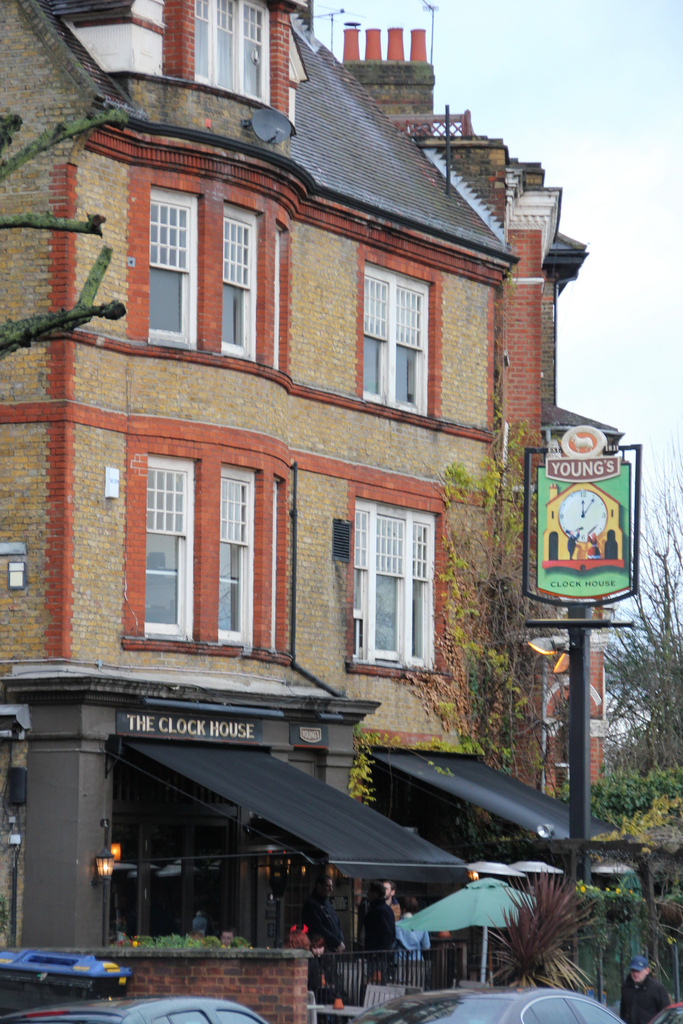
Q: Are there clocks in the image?
A: Yes, there is a clock.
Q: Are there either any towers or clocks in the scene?
A: Yes, there is a clock.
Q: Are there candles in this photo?
A: No, there are no candles.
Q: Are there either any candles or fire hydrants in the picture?
A: No, there are no candles or fire hydrants.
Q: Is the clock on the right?
A: Yes, the clock is on the right of the image.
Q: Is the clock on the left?
A: No, the clock is on the right of the image.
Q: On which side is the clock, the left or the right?
A: The clock is on the right of the image.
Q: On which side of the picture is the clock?
A: The clock is on the right of the image.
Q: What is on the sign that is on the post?
A: The clock is on the sign.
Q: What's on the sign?
A: The clock is on the sign.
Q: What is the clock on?
A: The clock is on the sign.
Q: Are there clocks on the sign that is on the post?
A: Yes, there is a clock on the sign.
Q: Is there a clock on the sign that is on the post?
A: Yes, there is a clock on the sign.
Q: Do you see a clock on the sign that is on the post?
A: Yes, there is a clock on the sign.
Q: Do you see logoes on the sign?
A: No, there is a clock on the sign.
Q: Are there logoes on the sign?
A: No, there is a clock on the sign.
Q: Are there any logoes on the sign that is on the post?
A: No, there is a clock on the sign.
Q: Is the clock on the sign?
A: Yes, the clock is on the sign.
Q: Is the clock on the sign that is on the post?
A: Yes, the clock is on the sign.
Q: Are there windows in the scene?
A: Yes, there is a window.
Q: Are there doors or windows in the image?
A: Yes, there is a window.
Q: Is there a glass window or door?
A: Yes, there is a glass window.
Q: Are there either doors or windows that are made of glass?
A: Yes, the window is made of glass.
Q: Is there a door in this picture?
A: No, there are no doors.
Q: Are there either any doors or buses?
A: No, there are no doors or buses.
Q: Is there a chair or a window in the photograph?
A: Yes, there is a window.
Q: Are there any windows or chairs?
A: Yes, there is a window.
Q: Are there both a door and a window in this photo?
A: No, there is a window but no doors.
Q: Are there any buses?
A: No, there are no buses.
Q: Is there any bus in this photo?
A: No, there are no buses.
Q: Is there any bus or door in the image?
A: No, there are no buses or doors.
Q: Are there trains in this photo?
A: No, there are no trains.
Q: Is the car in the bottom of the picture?
A: Yes, the car is in the bottom of the image.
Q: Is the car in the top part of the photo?
A: No, the car is in the bottom of the image.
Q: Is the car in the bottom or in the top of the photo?
A: The car is in the bottom of the image.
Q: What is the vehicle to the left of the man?
A: The vehicle is a car.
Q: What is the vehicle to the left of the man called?
A: The vehicle is a car.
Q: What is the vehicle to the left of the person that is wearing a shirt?
A: The vehicle is a car.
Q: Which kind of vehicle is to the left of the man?
A: The vehicle is a car.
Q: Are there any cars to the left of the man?
A: Yes, there is a car to the left of the man.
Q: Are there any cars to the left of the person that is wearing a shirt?
A: Yes, there is a car to the left of the man.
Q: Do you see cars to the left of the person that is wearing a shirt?
A: Yes, there is a car to the left of the man.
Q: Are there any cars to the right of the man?
A: No, the car is to the left of the man.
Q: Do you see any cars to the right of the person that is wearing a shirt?
A: No, the car is to the left of the man.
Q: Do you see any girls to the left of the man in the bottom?
A: No, there is a car to the left of the man.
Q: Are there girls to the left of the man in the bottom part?
A: No, there is a car to the left of the man.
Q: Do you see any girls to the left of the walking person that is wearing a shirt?
A: No, there is a car to the left of the man.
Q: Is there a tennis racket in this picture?
A: No, there are no rackets.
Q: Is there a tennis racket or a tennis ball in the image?
A: No, there are no rackets or tennis balls.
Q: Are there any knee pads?
A: No, there are no knee pads.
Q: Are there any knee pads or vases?
A: No, there are no knee pads or vases.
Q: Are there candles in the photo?
A: No, there are no candles.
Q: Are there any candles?
A: No, there are no candles.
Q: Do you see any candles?
A: No, there are no candles.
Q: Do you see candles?
A: No, there are no candles.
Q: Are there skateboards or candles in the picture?
A: No, there are no candles or skateboards.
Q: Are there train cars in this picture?
A: No, there are no train cars.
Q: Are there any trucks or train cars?
A: No, there are no train cars or trucks.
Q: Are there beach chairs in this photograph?
A: No, there are no beach chairs.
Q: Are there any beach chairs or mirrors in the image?
A: No, there are no beach chairs or mirrors.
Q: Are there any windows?
A: Yes, there is a window.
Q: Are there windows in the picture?
A: Yes, there is a window.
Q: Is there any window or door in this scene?
A: Yes, there is a window.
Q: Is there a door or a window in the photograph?
A: Yes, there is a window.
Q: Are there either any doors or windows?
A: Yes, there is a window.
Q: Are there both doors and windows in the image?
A: No, there is a window but no doors.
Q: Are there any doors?
A: No, there are no doors.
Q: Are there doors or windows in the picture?
A: Yes, there is a window.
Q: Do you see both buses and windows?
A: No, there is a window but no buses.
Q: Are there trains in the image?
A: No, there are no trains.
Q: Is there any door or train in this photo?
A: No, there are no trains or doors.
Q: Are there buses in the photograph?
A: No, there are no buses.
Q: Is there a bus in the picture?
A: No, there are no buses.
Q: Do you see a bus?
A: No, there are no buses.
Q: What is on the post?
A: The sign is on the post.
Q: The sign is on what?
A: The sign is on the post.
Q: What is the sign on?
A: The sign is on the post.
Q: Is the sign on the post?
A: Yes, the sign is on the post.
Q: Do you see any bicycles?
A: No, there are no bicycles.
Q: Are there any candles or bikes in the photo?
A: No, there are no bikes or candles.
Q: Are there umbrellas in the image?
A: Yes, there is an umbrella.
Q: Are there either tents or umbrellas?
A: Yes, there is an umbrella.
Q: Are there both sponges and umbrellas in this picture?
A: No, there is an umbrella but no sponges.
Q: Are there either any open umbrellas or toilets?
A: Yes, there is an open umbrella.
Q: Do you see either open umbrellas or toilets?
A: Yes, there is an open umbrella.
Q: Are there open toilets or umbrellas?
A: Yes, there is an open umbrella.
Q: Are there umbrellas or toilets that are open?
A: Yes, the umbrella is open.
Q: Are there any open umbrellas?
A: Yes, there is an open umbrella.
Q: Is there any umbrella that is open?
A: Yes, there is an umbrella that is open.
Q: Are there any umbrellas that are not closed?
A: Yes, there is a open umbrella.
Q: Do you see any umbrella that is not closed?
A: Yes, there is a open umbrella.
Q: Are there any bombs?
A: No, there are no bombs.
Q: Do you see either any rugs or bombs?
A: No, there are no bombs or rugs.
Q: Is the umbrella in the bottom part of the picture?
A: Yes, the umbrella is in the bottom of the image.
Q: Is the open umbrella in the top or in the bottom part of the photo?
A: The umbrella is in the bottom of the image.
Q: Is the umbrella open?
A: Yes, the umbrella is open.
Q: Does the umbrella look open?
A: Yes, the umbrella is open.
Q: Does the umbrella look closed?
A: No, the umbrella is open.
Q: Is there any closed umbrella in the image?
A: No, there is an umbrella but it is open.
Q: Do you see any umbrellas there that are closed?
A: No, there is an umbrella but it is open.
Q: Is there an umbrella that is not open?
A: No, there is an umbrella but it is open.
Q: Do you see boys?
A: No, there are no boys.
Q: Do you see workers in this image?
A: No, there are no workers.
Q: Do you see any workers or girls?
A: No, there are no workers or girls.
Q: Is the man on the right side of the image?
A: Yes, the man is on the right of the image.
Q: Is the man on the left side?
A: No, the man is on the right of the image.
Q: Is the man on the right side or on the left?
A: The man is on the right of the image.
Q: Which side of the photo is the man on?
A: The man is on the right of the image.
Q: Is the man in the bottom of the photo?
A: Yes, the man is in the bottom of the image.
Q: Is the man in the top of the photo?
A: No, the man is in the bottom of the image.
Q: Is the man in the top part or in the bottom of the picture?
A: The man is in the bottom of the image.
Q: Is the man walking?
A: Yes, the man is walking.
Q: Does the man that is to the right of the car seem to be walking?
A: Yes, the man is walking.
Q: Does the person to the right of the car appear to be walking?
A: Yes, the man is walking.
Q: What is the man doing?
A: The man is walking.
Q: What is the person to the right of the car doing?
A: The man is walking.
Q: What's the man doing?
A: The man is walking.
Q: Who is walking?
A: The man is walking.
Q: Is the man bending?
A: No, the man is walking.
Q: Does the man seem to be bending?
A: No, the man is walking.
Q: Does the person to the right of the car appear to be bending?
A: No, the man is walking.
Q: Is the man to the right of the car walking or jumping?
A: The man is walking.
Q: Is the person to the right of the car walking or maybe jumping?
A: The man is walking.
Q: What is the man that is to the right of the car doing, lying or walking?
A: The man is walking.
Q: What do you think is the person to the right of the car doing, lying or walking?
A: The man is walking.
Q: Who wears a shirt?
A: The man wears a shirt.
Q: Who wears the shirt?
A: The man wears a shirt.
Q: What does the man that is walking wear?
A: The man wears a shirt.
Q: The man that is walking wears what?
A: The man wears a shirt.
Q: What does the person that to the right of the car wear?
A: The man wears a shirt.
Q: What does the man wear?
A: The man wears a shirt.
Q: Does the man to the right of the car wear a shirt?
A: Yes, the man wears a shirt.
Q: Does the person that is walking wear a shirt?
A: Yes, the man wears a shirt.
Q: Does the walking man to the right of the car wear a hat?
A: No, the man wears a shirt.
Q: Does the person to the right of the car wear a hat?
A: No, the man wears a shirt.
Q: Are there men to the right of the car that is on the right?
A: Yes, there is a man to the right of the car.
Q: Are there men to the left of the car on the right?
A: No, the man is to the right of the car.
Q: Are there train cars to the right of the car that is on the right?
A: No, there is a man to the right of the car.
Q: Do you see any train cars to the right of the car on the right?
A: No, there is a man to the right of the car.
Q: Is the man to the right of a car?
A: Yes, the man is to the right of a car.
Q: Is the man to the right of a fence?
A: No, the man is to the right of a car.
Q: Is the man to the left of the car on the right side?
A: No, the man is to the right of the car.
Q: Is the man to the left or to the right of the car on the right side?
A: The man is to the right of the car.